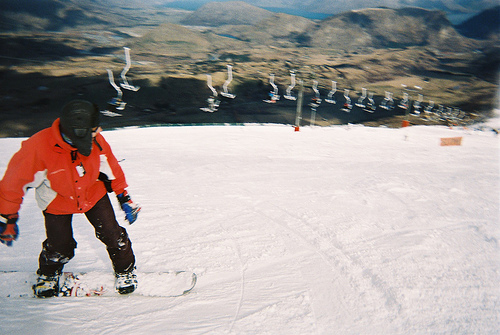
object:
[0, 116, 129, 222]
coat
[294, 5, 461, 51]
mountains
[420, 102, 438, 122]
ski lift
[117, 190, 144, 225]
glove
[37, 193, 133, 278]
pants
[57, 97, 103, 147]
head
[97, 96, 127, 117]
chair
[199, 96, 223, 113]
chair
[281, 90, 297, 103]
chair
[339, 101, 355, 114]
chair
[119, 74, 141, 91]
chair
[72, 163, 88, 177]
pass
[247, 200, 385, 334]
marks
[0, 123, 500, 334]
snow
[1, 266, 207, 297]
showboard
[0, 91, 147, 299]
person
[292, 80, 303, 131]
pole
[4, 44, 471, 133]
lift line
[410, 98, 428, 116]
lift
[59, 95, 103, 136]
helmet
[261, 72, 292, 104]
ski lift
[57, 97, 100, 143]
hat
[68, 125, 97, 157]
flaps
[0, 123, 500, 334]
ground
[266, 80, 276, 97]
person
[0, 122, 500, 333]
slope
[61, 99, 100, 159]
head covering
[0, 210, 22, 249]
glove